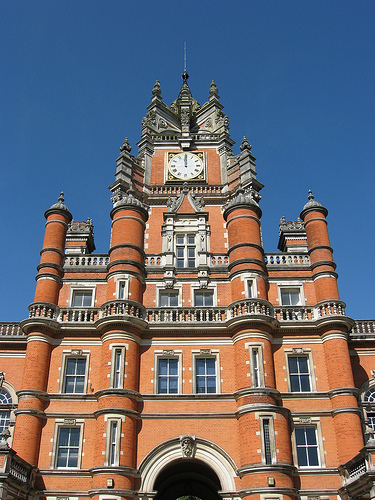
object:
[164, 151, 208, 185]
clock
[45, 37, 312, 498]
tower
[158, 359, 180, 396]
window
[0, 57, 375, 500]
building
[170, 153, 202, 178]
time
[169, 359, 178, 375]
panes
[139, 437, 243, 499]
archway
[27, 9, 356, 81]
sky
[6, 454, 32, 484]
railing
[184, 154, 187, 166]
hand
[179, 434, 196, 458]
statue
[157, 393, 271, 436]
wall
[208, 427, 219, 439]
brick